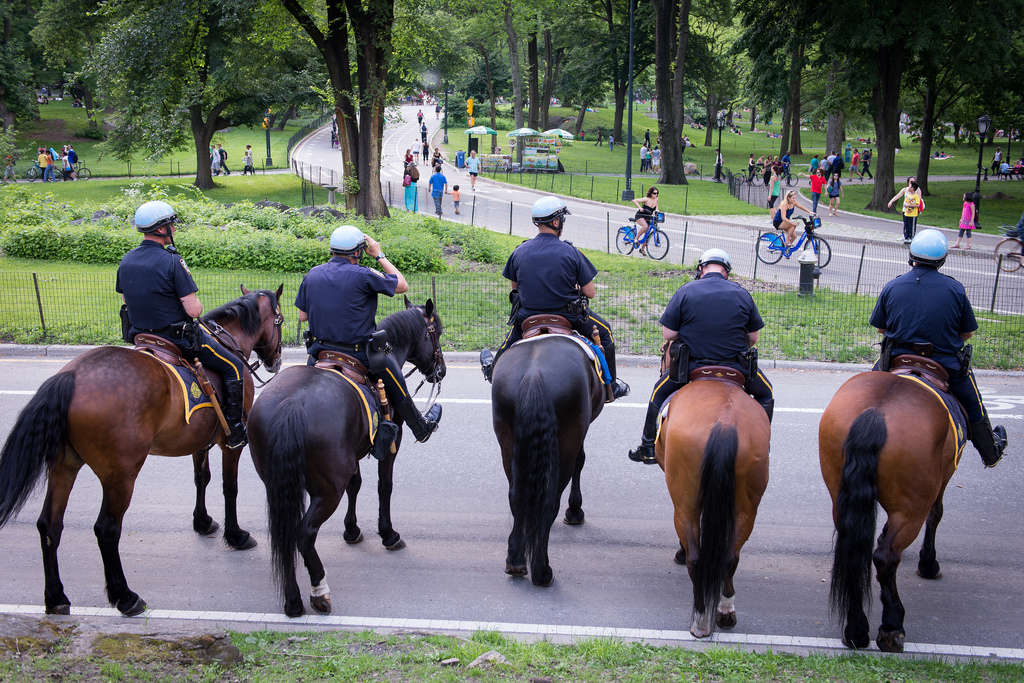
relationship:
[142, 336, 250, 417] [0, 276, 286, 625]
cloth on horse